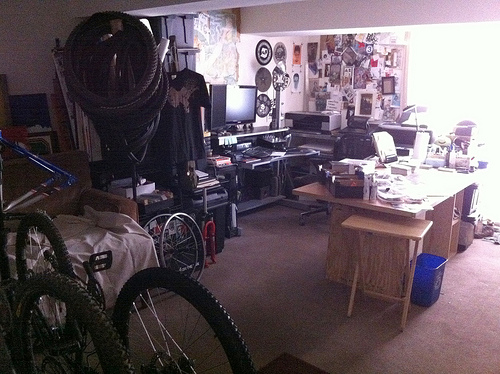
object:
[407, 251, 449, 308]
waste basket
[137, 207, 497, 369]
carpet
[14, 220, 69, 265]
tire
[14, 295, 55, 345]
spoke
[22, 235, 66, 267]
spoke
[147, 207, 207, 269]
tire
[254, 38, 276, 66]
pictures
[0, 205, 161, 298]
white truck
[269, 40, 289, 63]
sign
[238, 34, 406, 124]
wall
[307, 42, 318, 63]
sign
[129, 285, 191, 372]
spoke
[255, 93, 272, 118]
sign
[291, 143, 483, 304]
counter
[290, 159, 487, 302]
table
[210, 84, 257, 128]
tv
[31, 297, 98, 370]
metalspoke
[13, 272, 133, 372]
tire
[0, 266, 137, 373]
bicycle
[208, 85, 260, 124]
monitors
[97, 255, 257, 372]
tire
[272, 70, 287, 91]
sign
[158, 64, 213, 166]
shirt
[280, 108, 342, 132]
printer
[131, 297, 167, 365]
metal spoke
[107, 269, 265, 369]
tires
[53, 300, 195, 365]
spokes